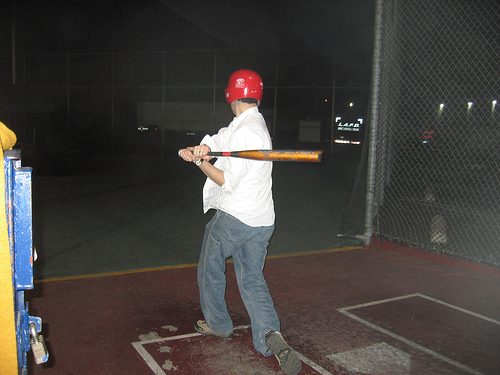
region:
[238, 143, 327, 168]
orange base ball bat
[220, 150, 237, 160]
red part on base ball bat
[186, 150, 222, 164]
black grip on bat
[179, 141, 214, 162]
hands holding bottom of bat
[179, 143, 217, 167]
hands holding grip of bat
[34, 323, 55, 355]
metal lock in corner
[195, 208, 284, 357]
jeans on man's legs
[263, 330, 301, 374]
black bottom of shoes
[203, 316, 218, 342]
brown tops of shoes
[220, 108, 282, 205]
white shirt on man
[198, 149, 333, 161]
batter getting ready to swing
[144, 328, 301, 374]
feet in batter's box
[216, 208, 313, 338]
person wearing blue jeans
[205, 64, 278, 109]
red helmet on the head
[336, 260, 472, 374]
white lines on the ground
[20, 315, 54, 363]
lock on the cage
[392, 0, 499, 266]
fence around the area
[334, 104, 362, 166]
lighted sign on the side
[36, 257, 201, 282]
yellow line seperating cage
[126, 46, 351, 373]
a man with a bat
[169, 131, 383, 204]
a gold and black bat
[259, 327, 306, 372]
the bottom of a shoe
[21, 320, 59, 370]
a silver pad lock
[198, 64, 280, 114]
a red helmet on head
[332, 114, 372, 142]
a white glowing sign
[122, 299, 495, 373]
white lines on the ground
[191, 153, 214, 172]
a watch on his wrist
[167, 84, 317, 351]
white shirt and blue jeans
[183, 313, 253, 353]
a tan and black shoe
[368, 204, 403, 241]
Small holes in the wired fence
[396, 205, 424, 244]
Small holes in the wired fence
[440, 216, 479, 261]
Small holes in the wired fence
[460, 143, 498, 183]
Small holes in the wired fence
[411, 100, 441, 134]
Small holes in the wired fence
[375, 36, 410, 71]
Small holes in the wired fence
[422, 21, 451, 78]
Small holes in the wired fence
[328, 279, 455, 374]
White lines on the pavement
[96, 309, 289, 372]
White lines on the pavement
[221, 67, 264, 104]
a man's red helmet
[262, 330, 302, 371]
a man's shoe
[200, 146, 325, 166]
a long gold bat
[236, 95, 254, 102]
part of a man's black hair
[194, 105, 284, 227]
a man's long sleeve white shirt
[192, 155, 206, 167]
a man's black watch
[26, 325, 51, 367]
a gray padlock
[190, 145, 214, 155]
the hand of a man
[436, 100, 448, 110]
a small light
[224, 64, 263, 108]
batting helmet is red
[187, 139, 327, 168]
man is holding a bat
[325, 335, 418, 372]
home plate is white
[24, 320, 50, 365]
lock on the box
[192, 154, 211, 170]
man is wearing a watch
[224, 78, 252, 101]
the hat is red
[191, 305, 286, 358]
shoes on the feet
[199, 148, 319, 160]
bat in the hand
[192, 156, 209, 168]
watch on the wrist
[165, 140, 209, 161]
hands of the man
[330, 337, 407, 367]
base on the field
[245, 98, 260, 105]
hair on the head